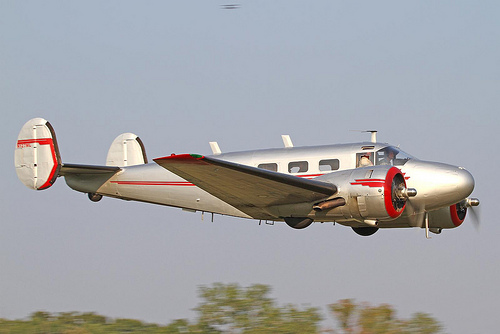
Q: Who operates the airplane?
A: Pilot.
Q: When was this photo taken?
A: Daytime.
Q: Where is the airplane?
A: In air.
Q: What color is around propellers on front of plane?
A: Red.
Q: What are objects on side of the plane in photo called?
A: Wings.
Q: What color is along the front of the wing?
A: Black.